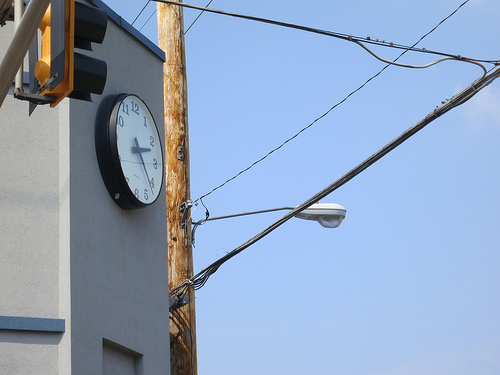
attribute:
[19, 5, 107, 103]
traffic signal — yellow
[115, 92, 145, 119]
numbers — black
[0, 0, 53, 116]
pole — metal, gray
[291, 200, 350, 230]
light — white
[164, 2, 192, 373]
power pole — tall, wooden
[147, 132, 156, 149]
number — 2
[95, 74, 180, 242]
clock — black, white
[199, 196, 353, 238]
lamp — connected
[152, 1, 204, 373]
pole — wooden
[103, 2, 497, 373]
sky — blue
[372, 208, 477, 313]
clouds — white